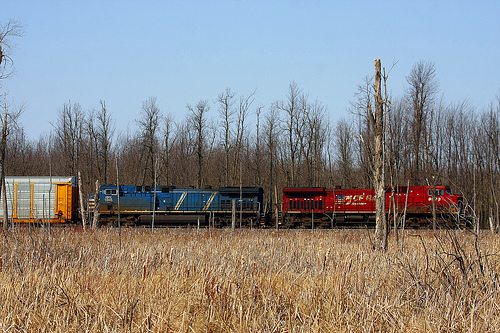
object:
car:
[0, 175, 80, 226]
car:
[89, 183, 264, 224]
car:
[280, 185, 465, 229]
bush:
[405, 192, 499, 325]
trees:
[1, 85, 498, 236]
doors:
[3, 180, 56, 220]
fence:
[2, 207, 498, 232]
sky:
[0, 0, 499, 151]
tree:
[405, 58, 436, 188]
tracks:
[3, 223, 495, 230]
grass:
[1, 225, 498, 331]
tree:
[368, 57, 388, 251]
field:
[1, 225, 498, 332]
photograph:
[1, 1, 499, 331]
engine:
[280, 187, 467, 227]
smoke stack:
[335, 184, 341, 192]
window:
[104, 187, 112, 196]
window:
[110, 189, 116, 195]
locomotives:
[1, 175, 467, 230]